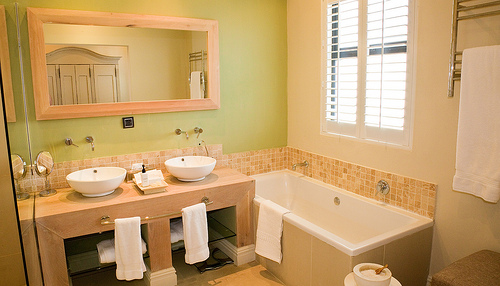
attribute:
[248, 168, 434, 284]
bathtub — deep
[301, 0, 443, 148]
blinds — white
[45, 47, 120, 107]
door reflection — brown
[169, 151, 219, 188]
sink — white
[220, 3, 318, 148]
wall — green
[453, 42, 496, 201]
towel — extra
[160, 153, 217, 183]
sink — white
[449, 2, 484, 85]
towel rack — metal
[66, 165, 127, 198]
basin — white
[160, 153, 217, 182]
basin — white